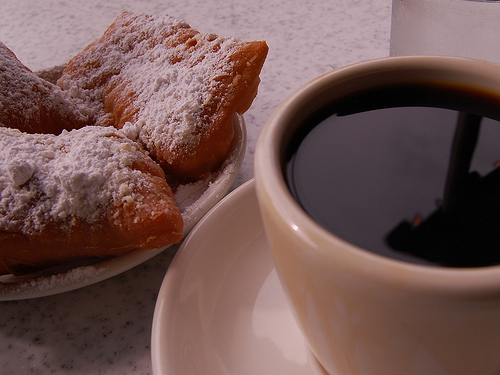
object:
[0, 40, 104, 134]
bread items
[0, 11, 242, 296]
powdered sugar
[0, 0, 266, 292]
pastries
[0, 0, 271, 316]
spots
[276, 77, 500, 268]
black coffee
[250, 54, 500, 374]
brown cup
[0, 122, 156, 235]
powder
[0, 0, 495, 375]
scene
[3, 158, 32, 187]
sugar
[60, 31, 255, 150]
powder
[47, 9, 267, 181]
bread item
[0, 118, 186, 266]
bread item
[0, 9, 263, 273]
treats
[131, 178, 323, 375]
plate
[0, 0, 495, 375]
table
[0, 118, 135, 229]
topping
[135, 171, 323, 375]
saucer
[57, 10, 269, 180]
donut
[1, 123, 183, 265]
donut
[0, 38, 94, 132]
donut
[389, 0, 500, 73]
floor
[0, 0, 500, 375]
breakfast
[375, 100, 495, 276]
reflection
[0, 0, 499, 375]
surface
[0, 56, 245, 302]
dish